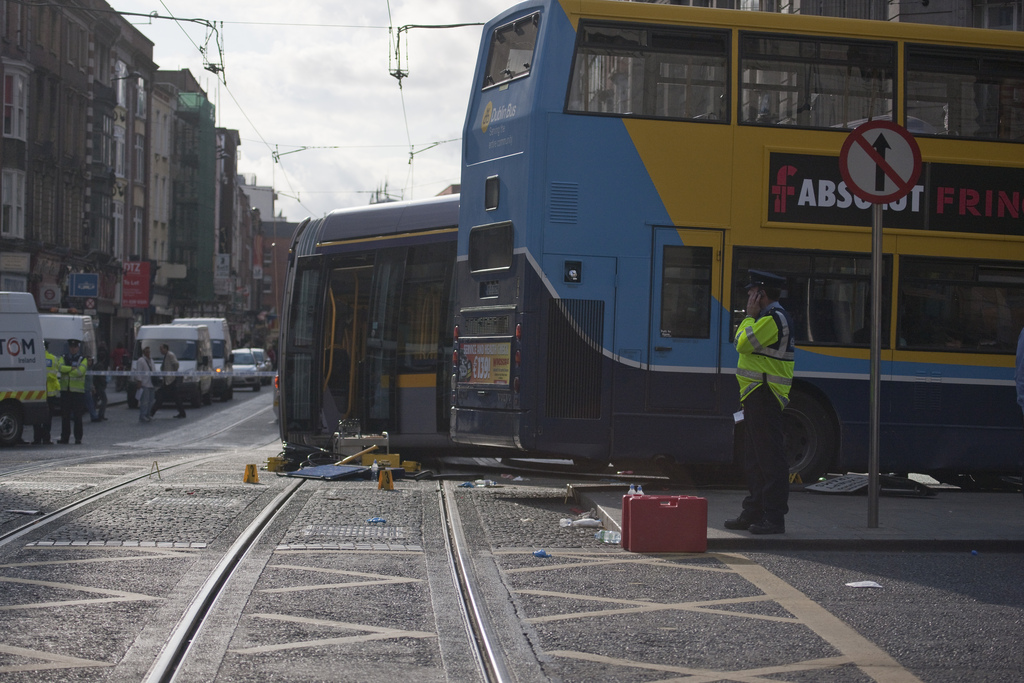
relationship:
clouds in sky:
[249, 101, 361, 197] [0, 3, 1024, 243]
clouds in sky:
[222, 56, 328, 120] [197, 14, 416, 201]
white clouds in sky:
[118, 0, 527, 220] [103, 6, 514, 219]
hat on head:
[743, 257, 797, 297] [734, 267, 788, 309]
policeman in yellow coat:
[721, 268, 817, 524] [724, 319, 802, 402]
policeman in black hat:
[721, 268, 817, 524] [728, 268, 792, 291]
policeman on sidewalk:
[724, 263, 800, 532] [574, 478, 1023, 552]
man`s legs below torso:
[724, 381, 791, 534] [733, 355, 790, 405]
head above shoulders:
[705, 266, 795, 334] [750, 311, 785, 341]